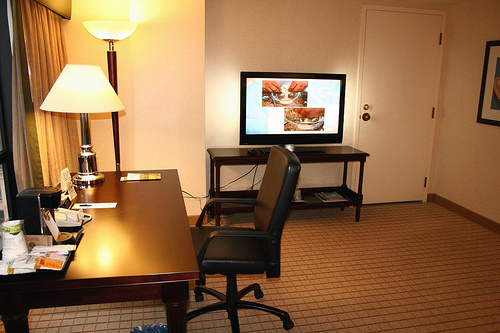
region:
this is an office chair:
[211, 146, 310, 325]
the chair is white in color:
[263, 176, 277, 202]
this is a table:
[125, 196, 177, 268]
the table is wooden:
[122, 200, 179, 278]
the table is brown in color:
[125, 191, 178, 261]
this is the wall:
[146, 45, 198, 132]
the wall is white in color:
[151, 51, 202, 137]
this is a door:
[368, 22, 428, 199]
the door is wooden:
[382, 40, 415, 93]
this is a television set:
[243, 75, 340, 140]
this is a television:
[238, 70, 355, 152]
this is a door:
[372, 10, 424, 215]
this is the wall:
[217, 8, 337, 49]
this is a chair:
[204, 200, 281, 272]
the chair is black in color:
[258, 173, 285, 201]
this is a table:
[113, 225, 183, 272]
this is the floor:
[328, 229, 465, 301]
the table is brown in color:
[112, 222, 174, 270]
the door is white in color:
[382, 35, 420, 96]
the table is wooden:
[88, 229, 185, 279]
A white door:
[363, 10, 448, 229]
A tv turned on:
[233, 63, 351, 142]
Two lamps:
[33, 3, 161, 196]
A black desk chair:
[171, 146, 320, 327]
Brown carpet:
[317, 225, 496, 330]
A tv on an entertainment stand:
[188, 53, 390, 248]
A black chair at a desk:
[1, 147, 308, 319]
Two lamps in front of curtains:
[0, 0, 130, 192]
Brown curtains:
[8, 0, 93, 188]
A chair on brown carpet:
[182, 143, 474, 322]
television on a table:
[229, 58, 353, 153]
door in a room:
[337, 1, 454, 218]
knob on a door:
[359, 108, 373, 125]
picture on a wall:
[466, 26, 499, 136]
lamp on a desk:
[31, 55, 133, 192]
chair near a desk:
[175, 135, 310, 332]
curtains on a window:
[5, 0, 87, 194]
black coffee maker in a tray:
[9, 178, 79, 248]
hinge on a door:
[423, 101, 443, 127]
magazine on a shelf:
[308, 185, 350, 210]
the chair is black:
[235, 154, 305, 294]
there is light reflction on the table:
[86, 217, 141, 266]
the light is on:
[35, 73, 157, 119]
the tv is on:
[238, 33, 365, 144]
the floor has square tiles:
[336, 261, 458, 326]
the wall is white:
[225, 43, 343, 58]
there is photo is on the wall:
[468, 45, 497, 133]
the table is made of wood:
[215, 144, 380, 214]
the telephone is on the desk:
[60, 206, 92, 229]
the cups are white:
[0, 219, 32, 262]